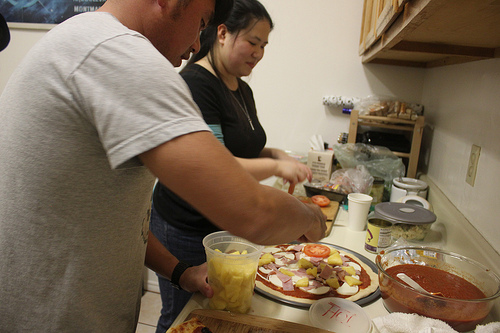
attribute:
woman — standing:
[9, 0, 499, 321]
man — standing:
[5, 1, 341, 328]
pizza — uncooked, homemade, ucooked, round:
[248, 237, 383, 303]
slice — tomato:
[305, 243, 328, 258]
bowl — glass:
[375, 241, 499, 324]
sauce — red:
[386, 263, 487, 316]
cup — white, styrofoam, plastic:
[343, 192, 375, 231]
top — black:
[153, 60, 269, 230]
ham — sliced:
[262, 255, 354, 291]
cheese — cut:
[208, 246, 255, 309]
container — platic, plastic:
[204, 232, 263, 316]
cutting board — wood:
[292, 194, 340, 234]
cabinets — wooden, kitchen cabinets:
[356, 1, 500, 75]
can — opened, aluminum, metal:
[364, 216, 396, 254]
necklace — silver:
[204, 53, 253, 129]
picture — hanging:
[1, 0, 102, 39]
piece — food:
[297, 276, 310, 289]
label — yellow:
[367, 224, 392, 251]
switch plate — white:
[462, 142, 482, 186]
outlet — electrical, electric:
[464, 142, 487, 190]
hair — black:
[180, 0, 275, 78]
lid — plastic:
[308, 296, 373, 331]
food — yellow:
[207, 248, 260, 315]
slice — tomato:
[309, 192, 329, 209]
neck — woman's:
[198, 54, 257, 93]